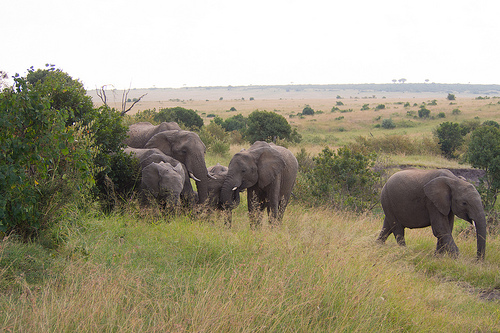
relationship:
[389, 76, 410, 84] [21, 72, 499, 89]
trees in distant horizon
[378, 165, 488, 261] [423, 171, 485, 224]
elephant has head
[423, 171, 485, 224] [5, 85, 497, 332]
head pointed towards ground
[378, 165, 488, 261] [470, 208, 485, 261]
elephant has trunk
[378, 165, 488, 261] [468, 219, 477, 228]
elephant has tusk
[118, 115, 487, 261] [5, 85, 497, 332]
elephants in ground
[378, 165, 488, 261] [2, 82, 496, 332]
elephant in grass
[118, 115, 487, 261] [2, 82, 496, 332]
elephants in grass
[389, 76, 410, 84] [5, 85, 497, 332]
trees in ground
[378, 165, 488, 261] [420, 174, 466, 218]
elephant has ears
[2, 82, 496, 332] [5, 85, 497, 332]
grass in ground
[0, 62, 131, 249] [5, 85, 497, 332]
bushes in ground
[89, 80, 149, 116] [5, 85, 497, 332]
tree in ground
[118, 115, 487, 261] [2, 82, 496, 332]
elephants on grass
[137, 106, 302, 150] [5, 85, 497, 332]
plants in ground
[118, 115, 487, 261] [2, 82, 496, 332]
elephants eating grass